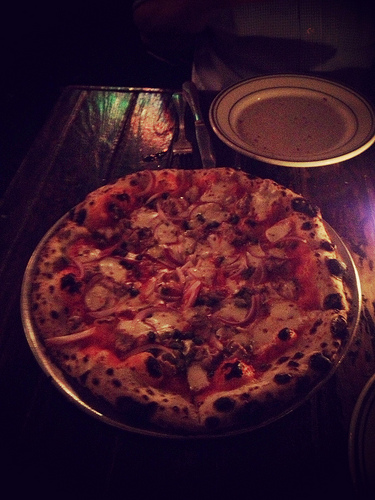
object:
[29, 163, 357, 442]
pizza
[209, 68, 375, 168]
plate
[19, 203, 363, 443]
platter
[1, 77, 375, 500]
table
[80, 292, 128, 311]
cheese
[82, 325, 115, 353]
tomato sauce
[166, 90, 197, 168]
fork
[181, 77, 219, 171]
knife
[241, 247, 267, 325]
onions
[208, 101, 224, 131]
lines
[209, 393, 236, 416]
circle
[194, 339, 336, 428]
crust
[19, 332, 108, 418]
edge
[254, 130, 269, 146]
crumb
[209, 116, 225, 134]
edge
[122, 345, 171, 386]
bubble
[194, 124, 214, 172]
blade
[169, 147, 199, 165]
tines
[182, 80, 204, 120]
handle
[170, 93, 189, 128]
handle